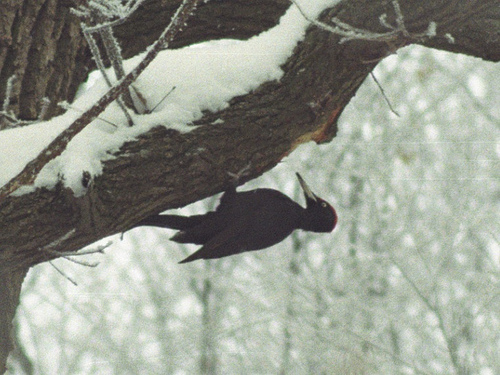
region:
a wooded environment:
[0, 0, 499, 374]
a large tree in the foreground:
[0, 0, 498, 374]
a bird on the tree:
[125, 160, 337, 264]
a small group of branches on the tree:
[42, 227, 114, 286]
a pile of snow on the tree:
[0, 0, 341, 197]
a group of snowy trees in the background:
[3, 43, 498, 374]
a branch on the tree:
[0, 0, 199, 200]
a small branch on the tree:
[366, 65, 401, 117]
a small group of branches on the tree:
[290, 0, 436, 65]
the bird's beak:
[295, 171, 317, 201]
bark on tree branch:
[108, 98, 330, 203]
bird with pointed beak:
[157, 172, 337, 264]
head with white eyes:
[294, 174, 339, 235]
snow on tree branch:
[6, 6, 365, 219]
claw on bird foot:
[222, 160, 254, 193]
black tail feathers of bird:
[137, 208, 227, 263]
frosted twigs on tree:
[312, 3, 440, 50]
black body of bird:
[180, 188, 295, 270]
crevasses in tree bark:
[6, 3, 87, 109]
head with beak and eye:
[299, 169, 339, 234]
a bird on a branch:
[141, 154, 383, 286]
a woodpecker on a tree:
[118, 123, 378, 277]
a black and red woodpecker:
[142, 157, 371, 263]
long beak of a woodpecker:
[288, 165, 333, 215]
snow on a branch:
[5, 36, 328, 205]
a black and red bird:
[146, 163, 376, 270]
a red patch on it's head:
[311, 186, 344, 238]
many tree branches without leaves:
[47, 103, 498, 368]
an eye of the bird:
[323, 199, 327, 213]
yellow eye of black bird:
[318, 196, 334, 221]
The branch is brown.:
[6, 8, 493, 260]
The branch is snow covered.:
[2, 7, 474, 236]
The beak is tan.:
[289, 167, 315, 200]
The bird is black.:
[160, 157, 355, 267]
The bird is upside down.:
[176, 152, 361, 277]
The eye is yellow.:
[315, 193, 332, 214]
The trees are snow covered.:
[10, 13, 498, 372]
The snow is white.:
[50, 50, 287, 119]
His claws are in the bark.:
[218, 152, 259, 189]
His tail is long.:
[127, 207, 207, 259]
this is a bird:
[140, 163, 365, 260]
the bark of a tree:
[114, 0, 219, 45]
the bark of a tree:
[18, 170, 130, 250]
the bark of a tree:
[106, 121, 266, 229]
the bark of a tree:
[256, 27, 357, 160]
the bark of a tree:
[1, 0, 107, 140]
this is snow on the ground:
[317, 273, 397, 334]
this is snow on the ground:
[390, 220, 466, 340]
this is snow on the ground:
[166, 40, 246, 117]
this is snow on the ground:
[35, 118, 92, 171]